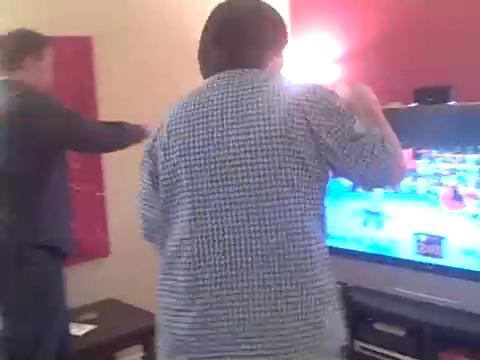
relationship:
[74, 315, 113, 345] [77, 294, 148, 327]
paper on table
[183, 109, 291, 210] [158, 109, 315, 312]
shirt on back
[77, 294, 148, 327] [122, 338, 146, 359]
table on ground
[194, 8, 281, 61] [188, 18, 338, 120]
hair on head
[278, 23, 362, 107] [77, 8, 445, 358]
light in room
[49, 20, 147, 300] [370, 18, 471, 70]
artwork on wall